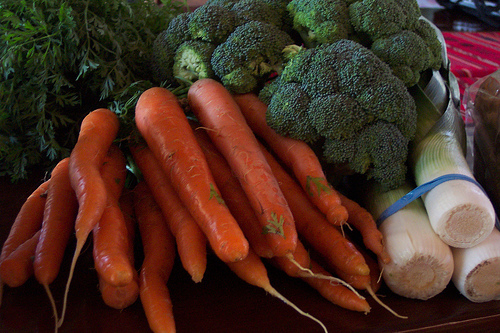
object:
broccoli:
[257, 38, 416, 193]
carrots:
[187, 78, 299, 263]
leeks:
[367, 184, 455, 299]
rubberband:
[373, 174, 499, 235]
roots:
[261, 285, 328, 333]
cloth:
[431, 29, 499, 126]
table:
[0, 274, 500, 333]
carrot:
[134, 85, 250, 264]